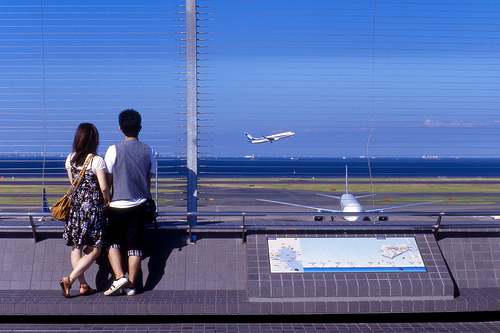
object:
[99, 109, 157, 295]
man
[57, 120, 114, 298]
woman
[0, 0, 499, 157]
sky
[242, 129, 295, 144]
plane